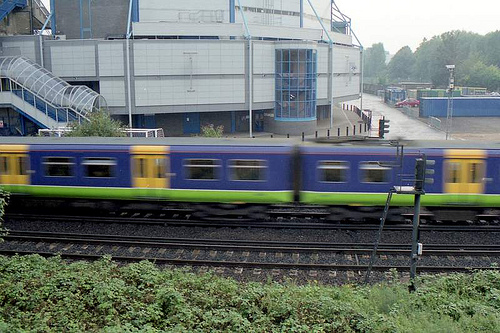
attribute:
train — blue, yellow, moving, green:
[1, 134, 499, 209]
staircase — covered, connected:
[1, 54, 119, 133]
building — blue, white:
[4, 3, 364, 137]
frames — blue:
[275, 100, 322, 123]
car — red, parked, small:
[397, 94, 416, 110]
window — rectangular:
[183, 157, 221, 182]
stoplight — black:
[403, 152, 428, 208]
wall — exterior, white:
[133, 40, 248, 115]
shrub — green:
[2, 253, 497, 331]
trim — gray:
[107, 102, 258, 116]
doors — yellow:
[128, 152, 171, 195]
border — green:
[2, 186, 499, 212]